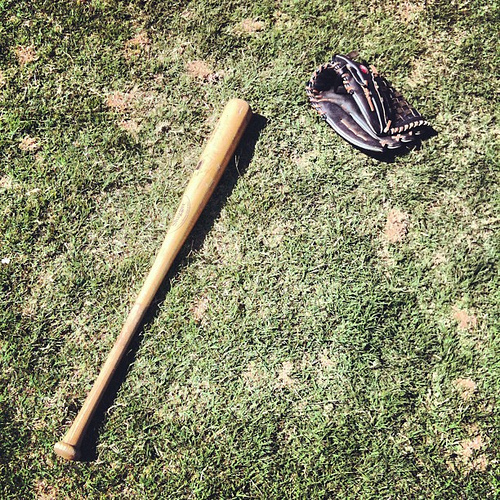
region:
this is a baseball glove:
[301, 42, 421, 149]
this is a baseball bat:
[45, 108, 275, 456]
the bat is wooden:
[160, 104, 252, 238]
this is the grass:
[222, 262, 459, 487]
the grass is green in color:
[240, 414, 364, 496]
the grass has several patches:
[218, 222, 390, 380]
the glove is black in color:
[335, 80, 387, 134]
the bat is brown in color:
[194, 177, 209, 201]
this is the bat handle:
[55, 417, 79, 461]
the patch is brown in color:
[104, 90, 156, 124]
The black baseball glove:
[297, 52, 432, 159]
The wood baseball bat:
[45, 93, 252, 461]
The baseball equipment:
[46, 48, 441, 468]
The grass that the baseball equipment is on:
[0, 1, 498, 498]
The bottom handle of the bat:
[47, 439, 84, 462]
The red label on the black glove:
[357, 61, 370, 73]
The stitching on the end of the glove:
[386, 120, 431, 135]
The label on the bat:
[158, 195, 191, 232]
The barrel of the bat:
[125, 97, 262, 263]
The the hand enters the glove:
[300, 55, 343, 102]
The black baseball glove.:
[305, 51, 436, 163]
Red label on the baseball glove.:
[357, 63, 369, 77]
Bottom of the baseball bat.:
[51, 441, 79, 460]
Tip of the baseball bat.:
[218, 98, 256, 115]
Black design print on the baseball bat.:
[168, 190, 191, 235]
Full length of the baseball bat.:
[51, 88, 250, 462]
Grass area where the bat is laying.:
[35, 81, 270, 473]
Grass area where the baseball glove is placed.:
[300, 48, 433, 169]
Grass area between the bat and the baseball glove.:
[246, 53, 316, 168]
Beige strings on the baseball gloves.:
[298, 62, 433, 160]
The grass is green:
[237, 227, 461, 447]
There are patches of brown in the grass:
[264, 280, 393, 440]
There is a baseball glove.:
[310, 56, 430, 182]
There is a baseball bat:
[34, 65, 282, 498]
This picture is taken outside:
[53, 65, 448, 496]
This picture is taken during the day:
[10, 20, 462, 477]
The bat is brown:
[117, 121, 284, 416]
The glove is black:
[308, 43, 468, 168]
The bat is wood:
[0, 29, 313, 481]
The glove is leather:
[279, 39, 496, 169]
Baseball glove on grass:
[303, 51, 437, 163]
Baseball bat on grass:
[52, 97, 252, 462]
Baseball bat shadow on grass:
[76, 112, 269, 463]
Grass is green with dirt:
[4, 1, 496, 497]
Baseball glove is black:
[305, 49, 436, 165]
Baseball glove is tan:
[52, 97, 251, 462]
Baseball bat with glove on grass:
[53, 50, 434, 462]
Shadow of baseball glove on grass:
[356, 125, 436, 164]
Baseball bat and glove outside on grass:
[1, 0, 496, 497]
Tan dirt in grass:
[93, 17, 213, 151]